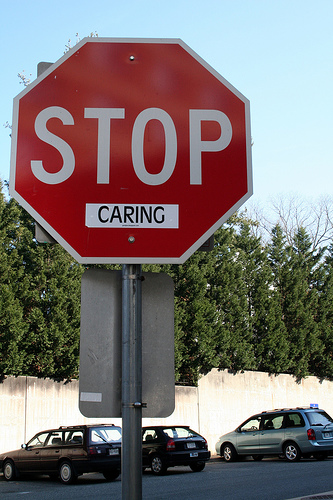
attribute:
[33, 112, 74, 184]
s — white, letter, written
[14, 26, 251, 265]
sign — stop, street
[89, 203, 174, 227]
sticker — white, black, graffiti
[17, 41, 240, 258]
stop sign — red, white, vandalized, hexagonal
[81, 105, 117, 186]
t — letter, written, white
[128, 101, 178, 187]
o — letter, written, white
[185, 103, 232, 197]
p — letter, written, white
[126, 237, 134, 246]
screw — bottom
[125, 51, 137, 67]
screw — top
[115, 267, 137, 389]
pole — metal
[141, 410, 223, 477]
car — small, black, middle, hatchback, parked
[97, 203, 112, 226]
c — letter, written, black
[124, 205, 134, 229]
r — letter, written, black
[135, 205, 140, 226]
i — letter, written, black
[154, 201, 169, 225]
g — letter, written, black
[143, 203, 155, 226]
n — letter, written, black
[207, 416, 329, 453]
van — grey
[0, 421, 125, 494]
station wagon — black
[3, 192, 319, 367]
trees — pine, green, row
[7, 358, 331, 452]
wall — stone, white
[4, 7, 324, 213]
sky — clear, blue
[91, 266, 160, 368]
sign — backwards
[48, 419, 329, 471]
cars — three, parked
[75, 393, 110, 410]
label — white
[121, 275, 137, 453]
signpost — metal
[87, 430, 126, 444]
window — rear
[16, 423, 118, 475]
hatchback — black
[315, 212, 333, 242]
branches — bare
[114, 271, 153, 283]
clamp — metal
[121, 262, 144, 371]
post — metal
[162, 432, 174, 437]
mirror — sideview